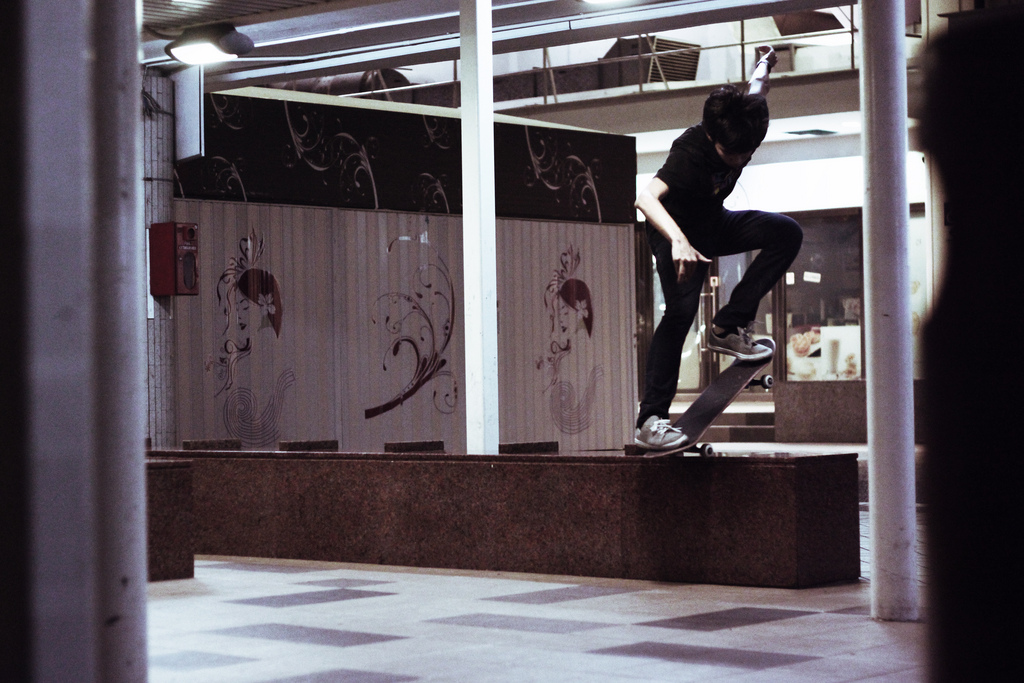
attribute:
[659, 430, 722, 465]
wheel — black, white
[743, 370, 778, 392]
wheel — black, white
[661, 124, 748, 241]
shirt — black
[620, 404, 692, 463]
sneaker — grey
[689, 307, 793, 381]
sneaker — grey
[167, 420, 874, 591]
fixture — stone, marble 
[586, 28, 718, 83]
vent — metal, air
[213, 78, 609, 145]
wall trim — white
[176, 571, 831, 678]
patterned flooring — black, white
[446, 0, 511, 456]
post — white, wooden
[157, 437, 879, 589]
surface — bench-type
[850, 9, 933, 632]
pole — white, round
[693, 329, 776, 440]
skateboard — black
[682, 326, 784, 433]
skateboard — tilted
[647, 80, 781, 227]
shirt — black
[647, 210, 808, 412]
pants — black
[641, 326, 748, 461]
shoes — white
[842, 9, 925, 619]
pole — white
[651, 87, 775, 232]
shirt — black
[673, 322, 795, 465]
skateboard — black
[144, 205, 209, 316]
box — red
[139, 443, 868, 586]
stone — marble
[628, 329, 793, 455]
sneakers — grey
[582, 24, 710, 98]
air vent — metal